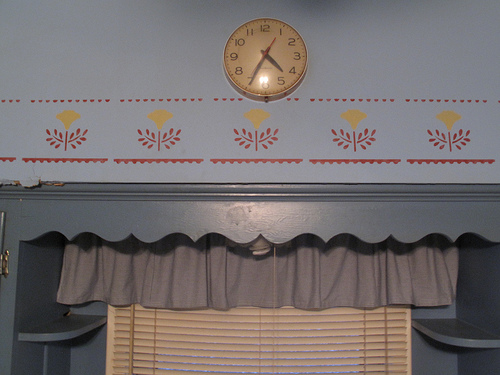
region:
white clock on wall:
[228, 18, 311, 103]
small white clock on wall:
[223, 10, 310, 107]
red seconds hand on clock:
[241, 33, 284, 82]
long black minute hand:
[240, 51, 277, 83]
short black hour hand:
[268, 53, 282, 68]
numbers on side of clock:
[231, 47, 254, 70]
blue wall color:
[1, 4, 149, 84]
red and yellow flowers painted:
[10, 92, 93, 184]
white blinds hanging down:
[151, 320, 358, 372]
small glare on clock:
[258, 67, 273, 79]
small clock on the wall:
[226, 22, 309, 109]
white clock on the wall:
[218, 9, 298, 106]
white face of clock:
[239, 30, 297, 81]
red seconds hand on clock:
[252, 33, 275, 69]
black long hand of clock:
[238, 41, 269, 87]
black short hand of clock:
[263, 50, 282, 67]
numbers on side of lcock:
[270, 25, 297, 42]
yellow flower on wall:
[46, 103, 88, 133]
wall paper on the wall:
[2, 73, 220, 187]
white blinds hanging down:
[209, 298, 364, 374]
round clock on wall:
[219, 15, 312, 102]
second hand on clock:
[247, 38, 277, 77]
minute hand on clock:
[246, 43, 269, 84]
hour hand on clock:
[260, 46, 282, 73]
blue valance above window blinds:
[49, 232, 463, 313]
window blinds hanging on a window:
[109, 303, 406, 373]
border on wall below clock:
[1, 89, 496, 167]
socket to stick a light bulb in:
[218, 236, 292, 263]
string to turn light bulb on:
[268, 244, 283, 359]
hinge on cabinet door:
[0, 249, 11, 276]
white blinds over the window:
[118, 298, 408, 374]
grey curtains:
[60, 244, 453, 304]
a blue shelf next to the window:
[26, 307, 94, 341]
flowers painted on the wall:
[4, 95, 497, 152]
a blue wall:
[3, 7, 205, 96]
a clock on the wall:
[215, 15, 306, 98]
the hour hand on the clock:
[265, 51, 285, 71]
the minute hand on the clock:
[245, 55, 262, 81]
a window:
[110, 265, 400, 370]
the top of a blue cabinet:
[3, 182, 496, 247]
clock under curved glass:
[223, 18, 307, 100]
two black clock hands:
[251, 47, 282, 82]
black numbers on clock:
[229, 23, 301, 90]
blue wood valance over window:
[7, 187, 499, 247]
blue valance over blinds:
[57, 246, 457, 310]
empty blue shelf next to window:
[413, 313, 493, 355]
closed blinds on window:
[109, 309, 409, 373]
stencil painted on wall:
[1, 93, 496, 165]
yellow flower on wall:
[147, 108, 174, 130]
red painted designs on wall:
[232, 125, 281, 150]